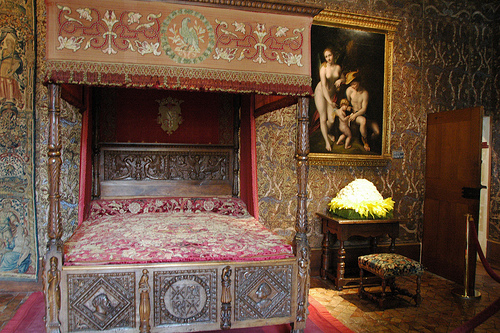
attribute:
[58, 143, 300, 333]
bed — old, ornate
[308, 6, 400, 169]
picture — hanging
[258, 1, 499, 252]
wallpaper — ornate, gold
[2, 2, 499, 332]
bedroom — old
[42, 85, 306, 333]
frame — wood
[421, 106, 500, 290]
door — open, brown, wooden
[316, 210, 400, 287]
table — wood, wooden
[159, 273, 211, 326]
emblem — round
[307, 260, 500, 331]
floor — tiled, tan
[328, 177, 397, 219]
arrangement — yellow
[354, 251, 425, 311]
stool — wooden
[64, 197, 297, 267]
bedspread — patterned, red, white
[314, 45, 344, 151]
person — nude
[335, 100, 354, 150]
person — nude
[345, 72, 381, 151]
person — nude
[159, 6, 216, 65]
circle — green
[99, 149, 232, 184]
carving — wooden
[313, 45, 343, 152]
lady — nude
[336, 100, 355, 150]
child — naked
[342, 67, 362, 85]
hat — brown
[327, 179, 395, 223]
flowers — yellow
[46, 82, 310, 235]
posts — wooden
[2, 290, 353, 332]
rug — red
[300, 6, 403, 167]
painting — antique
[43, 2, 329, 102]
canopy — red, brown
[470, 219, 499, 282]
rope — red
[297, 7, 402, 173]
frame — gold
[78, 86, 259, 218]
curtains — red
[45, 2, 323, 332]
bed — wooden